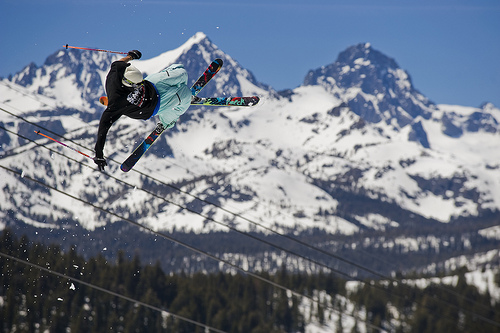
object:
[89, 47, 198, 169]
person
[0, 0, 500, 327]
air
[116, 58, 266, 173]
skis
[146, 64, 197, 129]
pants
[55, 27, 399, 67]
top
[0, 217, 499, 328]
trees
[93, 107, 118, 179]
arms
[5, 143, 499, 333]
wires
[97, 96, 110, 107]
stick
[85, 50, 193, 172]
jump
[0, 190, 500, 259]
background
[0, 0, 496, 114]
sky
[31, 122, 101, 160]
ski poles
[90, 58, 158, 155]
black top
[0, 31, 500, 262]
mountain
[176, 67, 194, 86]
knees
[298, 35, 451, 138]
mount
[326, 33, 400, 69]
peak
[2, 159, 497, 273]
trees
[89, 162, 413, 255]
ridge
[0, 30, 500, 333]
snow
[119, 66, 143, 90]
beanie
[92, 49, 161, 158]
sweatshirt